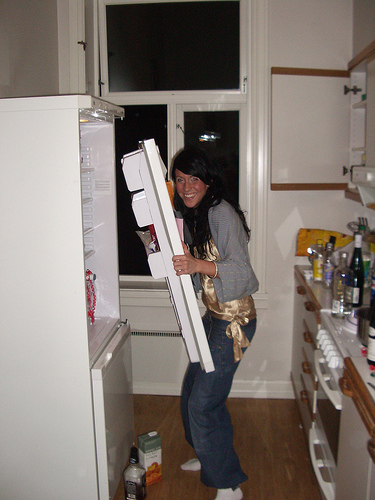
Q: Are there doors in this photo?
A: Yes, there is a door.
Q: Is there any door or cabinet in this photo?
A: Yes, there is a door.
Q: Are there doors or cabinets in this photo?
A: Yes, there is a door.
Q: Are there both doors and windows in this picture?
A: Yes, there are both a door and a window.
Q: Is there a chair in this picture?
A: No, there are no chairs.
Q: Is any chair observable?
A: No, there are no chairs.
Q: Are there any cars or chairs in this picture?
A: No, there are no chairs or cars.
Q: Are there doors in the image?
A: Yes, there is a door.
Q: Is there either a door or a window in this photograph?
A: Yes, there is a door.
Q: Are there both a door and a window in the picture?
A: Yes, there are both a door and a window.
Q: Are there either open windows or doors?
A: Yes, there is an open door.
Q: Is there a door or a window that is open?
A: Yes, the door is open.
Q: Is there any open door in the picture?
A: Yes, there is an open door.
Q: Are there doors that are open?
A: Yes, there is a door that is open.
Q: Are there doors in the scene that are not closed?
A: Yes, there is a open door.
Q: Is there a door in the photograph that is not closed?
A: Yes, there is a open door.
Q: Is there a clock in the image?
A: No, there are no clocks.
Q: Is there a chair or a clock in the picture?
A: No, there are no clocks or chairs.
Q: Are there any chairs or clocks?
A: No, there are no clocks or chairs.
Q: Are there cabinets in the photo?
A: Yes, there is a cabinet.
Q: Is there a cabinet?
A: Yes, there is a cabinet.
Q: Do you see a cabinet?
A: Yes, there is a cabinet.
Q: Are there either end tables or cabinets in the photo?
A: Yes, there is a cabinet.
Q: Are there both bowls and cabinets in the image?
A: No, there is a cabinet but no bowls.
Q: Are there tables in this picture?
A: No, there are no tables.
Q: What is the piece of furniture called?
A: The piece of furniture is a cabinet.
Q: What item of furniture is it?
A: The piece of furniture is a cabinet.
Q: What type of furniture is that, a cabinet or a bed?
A: This is a cabinet.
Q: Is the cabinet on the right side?
A: Yes, the cabinet is on the right of the image.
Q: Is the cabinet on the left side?
A: No, the cabinet is on the right of the image.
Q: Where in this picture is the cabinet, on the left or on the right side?
A: The cabinet is on the right of the image.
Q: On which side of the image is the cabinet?
A: The cabinet is on the right of the image.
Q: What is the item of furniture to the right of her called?
A: The piece of furniture is a cabinet.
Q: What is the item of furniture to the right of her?
A: The piece of furniture is a cabinet.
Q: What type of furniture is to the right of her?
A: The piece of furniture is a cabinet.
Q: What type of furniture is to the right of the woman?
A: The piece of furniture is a cabinet.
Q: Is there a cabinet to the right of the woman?
A: Yes, there is a cabinet to the right of the woman.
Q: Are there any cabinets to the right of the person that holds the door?
A: Yes, there is a cabinet to the right of the woman.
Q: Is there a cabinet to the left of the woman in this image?
A: No, the cabinet is to the right of the woman.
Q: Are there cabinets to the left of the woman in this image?
A: No, the cabinet is to the right of the woman.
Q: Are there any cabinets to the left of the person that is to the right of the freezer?
A: No, the cabinet is to the right of the woman.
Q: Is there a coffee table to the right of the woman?
A: No, there is a cabinet to the right of the woman.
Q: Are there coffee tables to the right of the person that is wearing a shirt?
A: No, there is a cabinet to the right of the woman.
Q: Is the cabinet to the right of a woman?
A: Yes, the cabinet is to the right of a woman.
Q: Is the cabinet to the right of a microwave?
A: No, the cabinet is to the right of a woman.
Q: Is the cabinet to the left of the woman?
A: No, the cabinet is to the right of the woman.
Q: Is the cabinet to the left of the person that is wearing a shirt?
A: No, the cabinet is to the right of the woman.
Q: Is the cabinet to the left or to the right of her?
A: The cabinet is to the right of the woman.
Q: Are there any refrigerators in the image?
A: Yes, there is a refrigerator.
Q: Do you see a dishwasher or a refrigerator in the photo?
A: Yes, there is a refrigerator.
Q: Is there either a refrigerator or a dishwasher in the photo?
A: Yes, there is a refrigerator.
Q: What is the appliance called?
A: The appliance is a refrigerator.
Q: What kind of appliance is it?
A: The appliance is a refrigerator.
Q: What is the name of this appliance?
A: That is a refrigerator.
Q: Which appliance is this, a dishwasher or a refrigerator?
A: That is a refrigerator.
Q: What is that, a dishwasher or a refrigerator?
A: That is a refrigerator.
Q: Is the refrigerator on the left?
A: Yes, the refrigerator is on the left of the image.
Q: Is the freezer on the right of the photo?
A: No, the freezer is on the left of the image.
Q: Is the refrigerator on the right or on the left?
A: The refrigerator is on the left of the image.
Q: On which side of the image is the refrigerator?
A: The refrigerator is on the left of the image.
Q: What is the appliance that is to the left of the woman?
A: The appliance is a refrigerator.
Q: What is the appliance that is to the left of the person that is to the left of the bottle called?
A: The appliance is a refrigerator.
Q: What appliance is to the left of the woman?
A: The appliance is a refrigerator.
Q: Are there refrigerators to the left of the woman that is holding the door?
A: Yes, there is a refrigerator to the left of the woman.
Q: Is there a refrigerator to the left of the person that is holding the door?
A: Yes, there is a refrigerator to the left of the woman.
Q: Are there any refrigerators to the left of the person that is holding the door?
A: Yes, there is a refrigerator to the left of the woman.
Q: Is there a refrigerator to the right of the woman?
A: No, the refrigerator is to the left of the woman.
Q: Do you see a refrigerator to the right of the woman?
A: No, the refrigerator is to the left of the woman.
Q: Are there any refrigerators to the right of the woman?
A: No, the refrigerator is to the left of the woman.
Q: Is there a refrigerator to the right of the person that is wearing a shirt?
A: No, the refrigerator is to the left of the woman.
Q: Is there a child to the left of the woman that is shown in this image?
A: No, there is a refrigerator to the left of the woman.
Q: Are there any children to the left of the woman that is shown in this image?
A: No, there is a refrigerator to the left of the woman.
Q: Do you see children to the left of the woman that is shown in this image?
A: No, there is a refrigerator to the left of the woman.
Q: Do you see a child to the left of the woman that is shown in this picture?
A: No, there is a refrigerator to the left of the woman.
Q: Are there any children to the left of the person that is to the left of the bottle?
A: No, there is a refrigerator to the left of the woman.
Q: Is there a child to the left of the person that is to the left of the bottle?
A: No, there is a refrigerator to the left of the woman.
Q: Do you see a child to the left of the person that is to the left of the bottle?
A: No, there is a refrigerator to the left of the woman.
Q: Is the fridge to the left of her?
A: Yes, the fridge is to the left of the woman.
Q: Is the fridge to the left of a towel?
A: No, the fridge is to the left of the woman.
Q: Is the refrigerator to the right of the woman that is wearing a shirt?
A: No, the refrigerator is to the left of the woman.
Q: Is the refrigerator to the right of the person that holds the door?
A: No, the refrigerator is to the left of the woman.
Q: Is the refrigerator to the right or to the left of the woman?
A: The refrigerator is to the left of the woman.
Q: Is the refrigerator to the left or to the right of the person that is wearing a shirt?
A: The refrigerator is to the left of the woman.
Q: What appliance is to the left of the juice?
A: The appliance is a refrigerator.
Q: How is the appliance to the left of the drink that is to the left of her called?
A: The appliance is a refrigerator.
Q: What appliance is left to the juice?
A: The appliance is a refrigerator.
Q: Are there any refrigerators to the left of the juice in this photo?
A: Yes, there is a refrigerator to the left of the juice.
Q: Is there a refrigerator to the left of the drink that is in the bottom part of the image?
A: Yes, there is a refrigerator to the left of the juice.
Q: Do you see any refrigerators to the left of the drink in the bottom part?
A: Yes, there is a refrigerator to the left of the juice.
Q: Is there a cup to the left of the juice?
A: No, there is a refrigerator to the left of the juice.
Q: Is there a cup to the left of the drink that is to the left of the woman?
A: No, there is a refrigerator to the left of the juice.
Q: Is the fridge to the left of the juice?
A: Yes, the fridge is to the left of the juice.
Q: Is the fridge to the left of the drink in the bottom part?
A: Yes, the fridge is to the left of the juice.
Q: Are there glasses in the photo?
A: No, there are no glasses.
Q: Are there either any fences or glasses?
A: No, there are no glasses or fences.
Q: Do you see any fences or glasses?
A: No, there are no glasses or fences.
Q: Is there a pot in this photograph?
A: Yes, there is a pot.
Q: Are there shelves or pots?
A: Yes, there is a pot.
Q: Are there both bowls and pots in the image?
A: No, there is a pot but no bowls.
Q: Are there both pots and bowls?
A: No, there is a pot but no bowls.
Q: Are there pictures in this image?
A: No, there are no pictures.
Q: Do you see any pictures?
A: No, there are no pictures.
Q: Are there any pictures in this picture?
A: No, there are no pictures.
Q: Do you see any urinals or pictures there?
A: No, there are no pictures or urinals.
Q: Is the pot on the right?
A: Yes, the pot is on the right of the image.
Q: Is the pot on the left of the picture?
A: No, the pot is on the right of the image.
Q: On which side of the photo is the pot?
A: The pot is on the right of the image.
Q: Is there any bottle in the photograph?
A: Yes, there is a bottle.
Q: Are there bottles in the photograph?
A: Yes, there is a bottle.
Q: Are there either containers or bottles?
A: Yes, there is a bottle.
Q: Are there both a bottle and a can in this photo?
A: No, there is a bottle but no cans.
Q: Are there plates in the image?
A: No, there are no plates.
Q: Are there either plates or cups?
A: No, there are no plates or cups.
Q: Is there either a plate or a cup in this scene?
A: No, there are no plates or cups.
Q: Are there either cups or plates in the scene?
A: No, there are no plates or cups.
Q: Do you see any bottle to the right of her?
A: Yes, there is a bottle to the right of the woman.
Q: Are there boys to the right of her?
A: No, there is a bottle to the right of the woman.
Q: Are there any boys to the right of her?
A: No, there is a bottle to the right of the woman.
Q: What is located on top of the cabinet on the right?
A: The bottle is on top of the cabinet.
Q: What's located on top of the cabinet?
A: The bottle is on top of the cabinet.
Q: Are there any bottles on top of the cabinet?
A: Yes, there is a bottle on top of the cabinet.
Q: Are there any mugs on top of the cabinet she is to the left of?
A: No, there is a bottle on top of the cabinet.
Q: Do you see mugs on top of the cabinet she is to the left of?
A: No, there is a bottle on top of the cabinet.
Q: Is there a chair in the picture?
A: No, there are no chairs.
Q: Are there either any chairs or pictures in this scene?
A: No, there are no chairs or pictures.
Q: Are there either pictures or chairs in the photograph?
A: No, there are no chairs or pictures.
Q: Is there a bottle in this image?
A: Yes, there is a bottle.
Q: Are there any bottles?
A: Yes, there is a bottle.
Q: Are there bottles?
A: Yes, there is a bottle.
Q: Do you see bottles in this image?
A: Yes, there is a bottle.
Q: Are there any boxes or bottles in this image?
A: Yes, there is a bottle.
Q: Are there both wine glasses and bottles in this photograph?
A: No, there is a bottle but no wine glasses.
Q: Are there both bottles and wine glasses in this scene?
A: No, there is a bottle but no wine glasses.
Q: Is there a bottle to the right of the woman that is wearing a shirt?
A: Yes, there is a bottle to the right of the woman.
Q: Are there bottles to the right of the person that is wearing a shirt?
A: Yes, there is a bottle to the right of the woman.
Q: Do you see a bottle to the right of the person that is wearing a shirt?
A: Yes, there is a bottle to the right of the woman.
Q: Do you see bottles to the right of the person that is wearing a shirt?
A: Yes, there is a bottle to the right of the woman.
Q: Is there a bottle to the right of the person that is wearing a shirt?
A: Yes, there is a bottle to the right of the woman.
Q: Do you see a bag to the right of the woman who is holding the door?
A: No, there is a bottle to the right of the woman.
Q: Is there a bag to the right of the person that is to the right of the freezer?
A: No, there is a bottle to the right of the woman.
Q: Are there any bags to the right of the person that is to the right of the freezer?
A: No, there is a bottle to the right of the woman.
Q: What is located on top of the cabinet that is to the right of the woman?
A: The bottle is on top of the cabinet.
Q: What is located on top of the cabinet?
A: The bottle is on top of the cabinet.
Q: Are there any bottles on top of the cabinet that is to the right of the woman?
A: Yes, there is a bottle on top of the cabinet.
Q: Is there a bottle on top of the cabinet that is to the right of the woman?
A: Yes, there is a bottle on top of the cabinet.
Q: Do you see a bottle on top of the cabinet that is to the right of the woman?
A: Yes, there is a bottle on top of the cabinet.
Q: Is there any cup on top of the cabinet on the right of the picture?
A: No, there is a bottle on top of the cabinet.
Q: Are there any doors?
A: Yes, there is a door.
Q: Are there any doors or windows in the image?
A: Yes, there is a door.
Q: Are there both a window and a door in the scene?
A: Yes, there are both a door and a window.